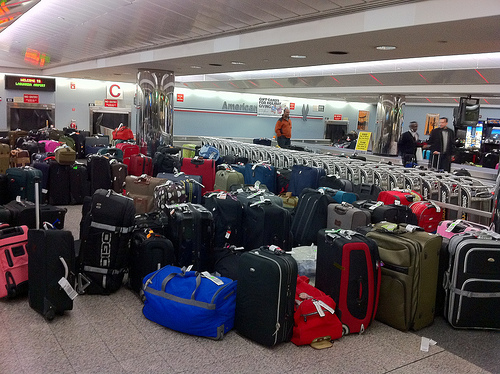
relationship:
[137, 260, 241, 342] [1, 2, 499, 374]
luggage at airport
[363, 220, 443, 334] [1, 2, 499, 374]
luggage at airport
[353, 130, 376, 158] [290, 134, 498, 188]
sign on carousel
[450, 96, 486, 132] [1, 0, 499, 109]
monitor from ceiling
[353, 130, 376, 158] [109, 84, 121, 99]
sign with letter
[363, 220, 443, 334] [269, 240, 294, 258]
luggage with tag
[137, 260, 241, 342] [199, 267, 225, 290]
luggage with tag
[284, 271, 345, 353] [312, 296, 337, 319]
bag with tag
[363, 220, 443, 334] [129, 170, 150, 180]
luggage with tag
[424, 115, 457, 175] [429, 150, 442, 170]
man holding handle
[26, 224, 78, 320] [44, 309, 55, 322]
bag has wheels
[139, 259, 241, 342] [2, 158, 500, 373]
duffel on floor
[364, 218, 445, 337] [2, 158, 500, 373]
suitcase on floor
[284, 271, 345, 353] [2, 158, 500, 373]
bag on floor